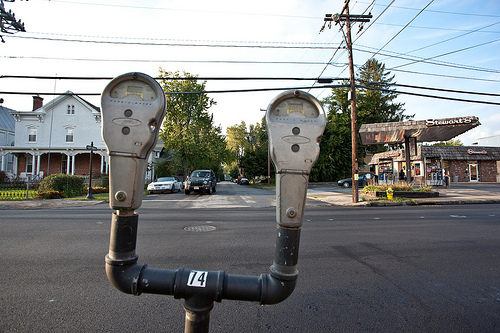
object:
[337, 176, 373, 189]
car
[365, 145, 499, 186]
store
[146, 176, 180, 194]
car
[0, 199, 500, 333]
road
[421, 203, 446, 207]
storm drain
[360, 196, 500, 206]
curb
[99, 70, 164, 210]
parking meter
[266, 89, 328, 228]
parking meter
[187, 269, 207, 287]
74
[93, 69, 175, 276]
meters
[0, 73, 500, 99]
wires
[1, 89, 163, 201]
house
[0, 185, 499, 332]
street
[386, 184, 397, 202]
hydrant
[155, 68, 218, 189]
trees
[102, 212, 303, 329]
pipe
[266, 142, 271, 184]
post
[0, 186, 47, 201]
grass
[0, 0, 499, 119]
sky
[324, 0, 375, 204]
utility pole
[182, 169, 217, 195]
vehicles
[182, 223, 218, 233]
sewer cover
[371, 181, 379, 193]
tall grass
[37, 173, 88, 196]
bush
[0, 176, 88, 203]
fence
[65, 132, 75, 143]
window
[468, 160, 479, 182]
door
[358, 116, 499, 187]
gas pumps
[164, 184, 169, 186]
headlights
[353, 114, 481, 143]
roof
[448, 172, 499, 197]
corner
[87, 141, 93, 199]
street sign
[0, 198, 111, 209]
sidewalk